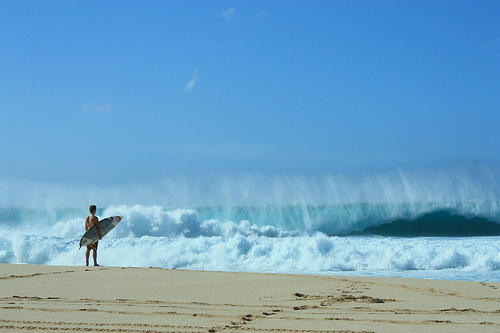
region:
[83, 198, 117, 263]
Boy standing by the ocean.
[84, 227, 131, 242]
Blue and white surfboard in hand.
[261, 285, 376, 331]
Foot prints in the dirt.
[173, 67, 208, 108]
Thin cloud in the sky.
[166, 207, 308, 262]
Big wave of water against the dirt.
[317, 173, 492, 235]
Big splash of water on other side.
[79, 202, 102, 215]
Top of man's head near water.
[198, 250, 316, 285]
Line of where dirt meets the water.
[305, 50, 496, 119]
Clear skies above the water.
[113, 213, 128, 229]
Red band across surfboard.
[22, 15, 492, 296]
picture taken outdoors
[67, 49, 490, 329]
picture taken during the day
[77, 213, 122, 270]
a man on a beach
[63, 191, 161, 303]
the man holds a surfboard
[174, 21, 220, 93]
small clouds in the sky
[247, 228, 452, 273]
the waves are crashing down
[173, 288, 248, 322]
lines in the sand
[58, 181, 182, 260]
the man looking at the waves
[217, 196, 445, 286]
the water is the ocean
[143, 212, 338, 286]
the waves are white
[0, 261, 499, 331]
A large area of sandy beach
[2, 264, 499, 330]
Many tracks in the sand of a beach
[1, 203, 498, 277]
vast expanse of ocean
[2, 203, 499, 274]
Large rolling white waves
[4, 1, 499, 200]
A clear blue sky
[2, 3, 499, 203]
A clear sunny sky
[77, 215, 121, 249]
A large surfboard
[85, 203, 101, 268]
A man standing on a beach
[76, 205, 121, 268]
A man standing on a beach with a surfboard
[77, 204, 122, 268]
A man on a beach looking at waves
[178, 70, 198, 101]
a white cloud in the sky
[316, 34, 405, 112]
a patch of clear blue sky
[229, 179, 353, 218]
light spray from an ocean wave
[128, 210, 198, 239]
the white water of a crashing ocean wave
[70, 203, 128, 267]
a man holding a surfboard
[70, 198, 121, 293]
a man on the beach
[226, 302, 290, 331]
footprints in the sand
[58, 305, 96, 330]
tire tracks in the sand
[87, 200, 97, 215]
the head of a person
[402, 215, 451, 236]
turquoise colored water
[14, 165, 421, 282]
a man in front the ocean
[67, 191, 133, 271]
surfer holding a surfboard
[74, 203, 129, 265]
surfboard under a right arm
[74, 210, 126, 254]
surfboard is gray and white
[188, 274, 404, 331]
footsteps on sand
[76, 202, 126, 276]
surfer is barefeet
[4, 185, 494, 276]
big waves in the ocean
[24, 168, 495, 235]
white splashes above the waves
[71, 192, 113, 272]
man is facing the ocean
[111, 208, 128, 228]
a design on nose of surfboard